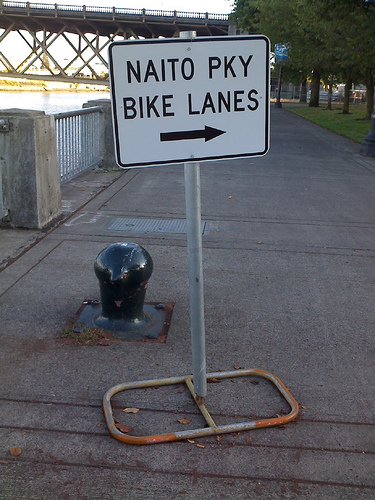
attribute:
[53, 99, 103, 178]
fence — silver 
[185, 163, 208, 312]
stand — metal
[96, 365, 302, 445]
stand bottom — metal , rusted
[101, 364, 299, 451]
stand — rusted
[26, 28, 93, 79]
bridge — tall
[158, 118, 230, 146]
arrow — black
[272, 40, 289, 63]
sign —  blue